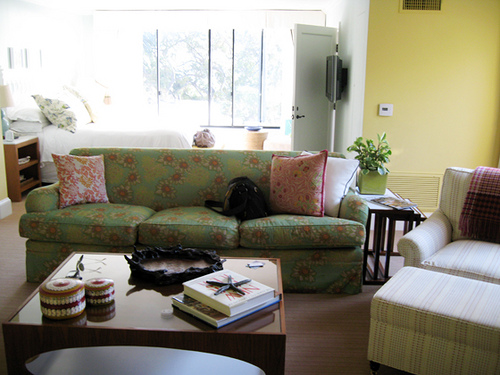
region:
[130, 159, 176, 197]
the couch has flowers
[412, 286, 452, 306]
the foot stool is white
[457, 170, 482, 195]
the throw is over the chair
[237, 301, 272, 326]
the books are on the table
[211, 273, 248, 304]
the star fish is on the books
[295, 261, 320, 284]
the flower is yellow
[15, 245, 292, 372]
a coffee table sitting in the living room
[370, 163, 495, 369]
a striped chair and ottoman sitting together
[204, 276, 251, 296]
a starfish sitting on the books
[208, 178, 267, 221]
the backpack sitting on the couch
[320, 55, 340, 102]
a tv attached to the wall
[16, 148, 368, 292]
the colorful couch sitting in the middle of the room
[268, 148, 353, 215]
some pillows sitting on the side of the couch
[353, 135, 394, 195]
the plant sitting on the endtable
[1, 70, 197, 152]
the bed sitting by the window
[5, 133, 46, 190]
a nightstand by the bed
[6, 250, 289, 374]
coffee table centrally located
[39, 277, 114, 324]
two decorative containers on the table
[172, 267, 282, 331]
two coffee table books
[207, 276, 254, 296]
starfish on the top book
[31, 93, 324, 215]
pink and green couch pillows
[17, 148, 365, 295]
mostly green couch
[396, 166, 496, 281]
white & stripes patterned chair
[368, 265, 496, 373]
white and stripes patterned ottoman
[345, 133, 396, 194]
green plant on end table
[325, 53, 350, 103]
television on the wall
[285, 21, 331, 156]
White door on wall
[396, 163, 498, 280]
Cream colored chair in living room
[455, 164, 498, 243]
Red plaid blanket on chair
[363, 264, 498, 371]
Cream colored ottoman in living room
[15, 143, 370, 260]
Green couch with flowers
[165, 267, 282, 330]
Two books on coffee table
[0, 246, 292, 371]
Wooden coffee table on floor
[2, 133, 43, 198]
End table next to bed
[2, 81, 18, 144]
Lamp sitting on end table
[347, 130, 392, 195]
Plant in yellow flower pot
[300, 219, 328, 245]
Small florap pattern on a couch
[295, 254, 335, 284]
Small florap pattern on a couch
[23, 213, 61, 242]
Small florap pattern on a couch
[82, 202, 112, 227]
Small florap pattern on a couch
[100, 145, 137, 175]
Small florap pattern on a couch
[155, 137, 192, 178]
Small florap pattern on a couch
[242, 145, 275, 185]
Small florap pattern on a couch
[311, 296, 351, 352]
a wooden floor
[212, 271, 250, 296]
a starfish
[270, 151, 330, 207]
a pillow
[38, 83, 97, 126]
a pillow on the bed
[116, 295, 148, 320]
table is brown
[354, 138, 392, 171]
a green plant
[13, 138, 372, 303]
the couch is color green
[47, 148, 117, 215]
pillow is on the couch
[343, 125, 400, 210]
a pot on the table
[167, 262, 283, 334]
books on the table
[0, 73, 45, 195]
lamp on a shelf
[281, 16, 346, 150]
the door is open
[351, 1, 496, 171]
the wall is yellow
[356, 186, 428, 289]
teh side table is brown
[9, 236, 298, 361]
the center table is square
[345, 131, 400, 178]
the plant is green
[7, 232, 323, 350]
a coffee table with several items on it